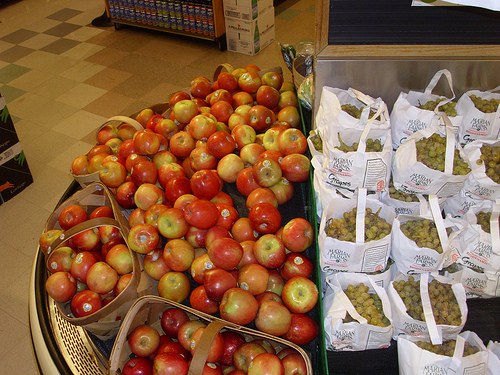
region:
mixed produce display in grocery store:
[38, 56, 495, 373]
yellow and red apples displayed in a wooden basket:
[33, 176, 151, 331]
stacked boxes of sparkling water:
[217, 2, 287, 53]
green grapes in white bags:
[309, 90, 498, 374]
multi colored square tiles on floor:
[3, 11, 228, 205]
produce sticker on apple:
[78, 301, 93, 314]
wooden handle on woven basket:
[35, 209, 134, 262]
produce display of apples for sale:
[41, 61, 324, 373]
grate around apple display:
[44, 293, 101, 369]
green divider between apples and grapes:
[296, 98, 333, 373]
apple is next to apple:
[218, 288, 259, 325]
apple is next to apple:
[43, 271, 74, 303]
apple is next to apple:
[278, 127, 307, 154]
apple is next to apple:
[173, 98, 200, 122]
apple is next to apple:
[99, 157, 124, 185]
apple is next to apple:
[255, 81, 278, 106]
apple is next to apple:
[128, 219, 159, 250]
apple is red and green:
[34, 61, 321, 373]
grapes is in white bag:
[304, 65, 496, 371]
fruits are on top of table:
[24, 56, 499, 373]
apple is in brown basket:
[34, 178, 152, 342]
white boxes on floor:
[218, 0, 281, 60]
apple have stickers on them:
[34, 60, 325, 372]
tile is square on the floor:
[4, 1, 334, 371]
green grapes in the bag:
[343, 268, 383, 333]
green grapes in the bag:
[405, 140, 479, 192]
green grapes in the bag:
[315, 126, 394, 173]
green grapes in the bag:
[363, 278, 447, 334]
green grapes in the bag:
[321, 187, 400, 292]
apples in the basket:
[46, 185, 142, 345]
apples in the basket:
[31, 72, 154, 187]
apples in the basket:
[124, 292, 296, 374]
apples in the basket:
[15, 156, 165, 318]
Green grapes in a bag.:
[326, 272, 391, 352]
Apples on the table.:
[35, 54, 317, 372]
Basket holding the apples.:
[104, 293, 310, 373]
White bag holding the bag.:
[325, 270, 390, 352]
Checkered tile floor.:
[2, 0, 304, 374]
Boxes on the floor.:
[222, 0, 277, 57]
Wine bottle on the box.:
[251, 18, 263, 53]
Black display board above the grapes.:
[310, 0, 497, 56]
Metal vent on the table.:
[35, 284, 106, 374]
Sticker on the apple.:
[289, 253, 304, 268]